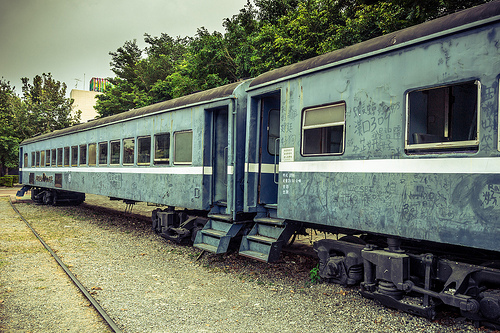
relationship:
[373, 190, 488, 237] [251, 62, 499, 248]
graffiti on train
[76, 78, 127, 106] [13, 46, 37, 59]
building in background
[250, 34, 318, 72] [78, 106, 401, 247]
trees by trains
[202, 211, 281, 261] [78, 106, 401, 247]
stairs to trains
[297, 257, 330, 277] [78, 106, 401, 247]
weeds under trains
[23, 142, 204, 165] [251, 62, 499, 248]
windows on train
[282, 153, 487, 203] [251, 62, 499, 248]
stripe on train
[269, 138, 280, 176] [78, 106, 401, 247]
handle on trains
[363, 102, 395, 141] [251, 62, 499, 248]
number on train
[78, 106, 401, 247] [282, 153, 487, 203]
trains have stripe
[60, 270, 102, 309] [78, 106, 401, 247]
rail for trains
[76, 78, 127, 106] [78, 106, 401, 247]
building behind trains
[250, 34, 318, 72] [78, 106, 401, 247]
trees behind trains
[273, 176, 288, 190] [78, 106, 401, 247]
letters on trains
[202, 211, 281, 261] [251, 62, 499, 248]
stairs to train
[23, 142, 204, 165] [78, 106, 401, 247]
windows on trains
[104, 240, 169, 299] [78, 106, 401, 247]
gravel under trains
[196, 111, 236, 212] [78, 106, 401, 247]
doorway to trains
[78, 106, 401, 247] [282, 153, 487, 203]
trains with stripe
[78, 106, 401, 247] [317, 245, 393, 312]
trains have wheels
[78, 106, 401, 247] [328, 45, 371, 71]
trains have roof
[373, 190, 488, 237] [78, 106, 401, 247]
graffiti on trains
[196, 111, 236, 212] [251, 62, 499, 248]
doorway to train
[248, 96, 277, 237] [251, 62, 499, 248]
doorway to train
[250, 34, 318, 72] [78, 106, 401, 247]
trees over trains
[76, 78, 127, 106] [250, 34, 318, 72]
building behind trees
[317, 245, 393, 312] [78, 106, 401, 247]
wheels under trains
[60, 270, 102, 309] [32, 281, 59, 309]
rail on ground